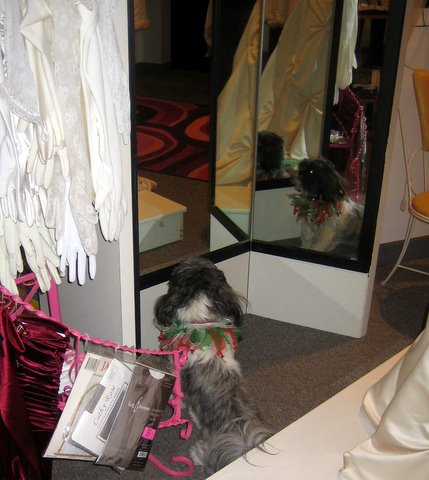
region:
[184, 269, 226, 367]
this is fur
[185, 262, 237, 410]
the fur is grey,white and black in color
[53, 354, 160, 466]
this is a magazine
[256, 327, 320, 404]
this is the floor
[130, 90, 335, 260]
this is the mirror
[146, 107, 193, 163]
this is a carpet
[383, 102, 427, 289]
this is a seat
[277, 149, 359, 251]
this is a dog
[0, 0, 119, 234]
these are clothes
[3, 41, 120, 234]
the clothes are white in color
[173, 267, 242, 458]
this is a pet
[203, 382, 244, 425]
the pet has many fur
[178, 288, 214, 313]
the pet has black and white color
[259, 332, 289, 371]
this is a floor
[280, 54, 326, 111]
this is a glass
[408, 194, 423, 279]
this is a chair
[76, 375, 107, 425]
this is a magazine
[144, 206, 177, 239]
this is a box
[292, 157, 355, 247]
this is the reflection of the pet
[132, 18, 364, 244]
the wardrobe is wide opened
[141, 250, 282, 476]
A dog is sitting in a store.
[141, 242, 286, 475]
A dog is sitting on a floor.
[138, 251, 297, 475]
A dog's colors are white, black, and gray.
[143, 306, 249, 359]
A dog is wearing a colored item around it's neck.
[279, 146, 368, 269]
A dog's reflection can be seen in a mirror.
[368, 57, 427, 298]
A chair is against a wall.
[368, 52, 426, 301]
A chair's colors are yellow and white.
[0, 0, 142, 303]
Clothing is hanging in a store.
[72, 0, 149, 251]
A white piece of clothing is hanging in a store.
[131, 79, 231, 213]
A brown and red object can be seen in a reflection.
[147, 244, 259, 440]
the dog is sitting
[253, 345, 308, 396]
the ground is gray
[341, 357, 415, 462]
the sheet is white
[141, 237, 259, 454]
the dog is gray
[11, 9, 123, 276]
the clothes are white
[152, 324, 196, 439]
the leash is pink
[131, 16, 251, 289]
the mirror is tall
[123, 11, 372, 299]
there are two mirrors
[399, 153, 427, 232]
the chair is brown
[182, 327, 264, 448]
the fur is long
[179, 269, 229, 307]
this is fur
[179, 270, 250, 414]
the fur is white and black in color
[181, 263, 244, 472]
this is a pet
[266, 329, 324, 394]
this is the floor of the house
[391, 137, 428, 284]
this is a chair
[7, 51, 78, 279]
the clothes is white in color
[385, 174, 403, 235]
this is the wall